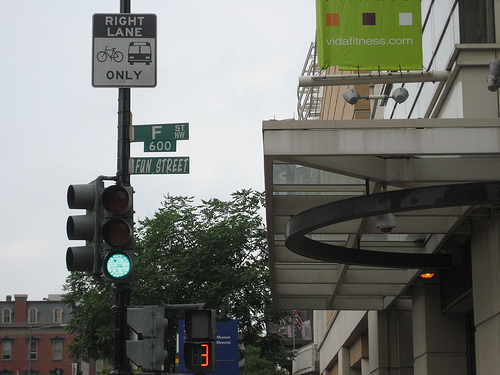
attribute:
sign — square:
[90, 12, 156, 88]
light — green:
[100, 251, 133, 279]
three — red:
[198, 344, 209, 369]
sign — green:
[316, 1, 423, 71]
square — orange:
[325, 14, 339, 25]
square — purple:
[363, 12, 375, 26]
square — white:
[400, 11, 413, 27]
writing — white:
[327, 38, 414, 45]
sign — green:
[130, 123, 187, 150]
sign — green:
[133, 158, 191, 174]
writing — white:
[150, 124, 180, 150]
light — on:
[421, 267, 435, 281]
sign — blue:
[218, 323, 239, 374]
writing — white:
[104, 14, 146, 38]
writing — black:
[106, 71, 144, 82]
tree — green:
[138, 218, 266, 298]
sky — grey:
[163, 5, 294, 94]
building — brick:
[1, 300, 74, 374]